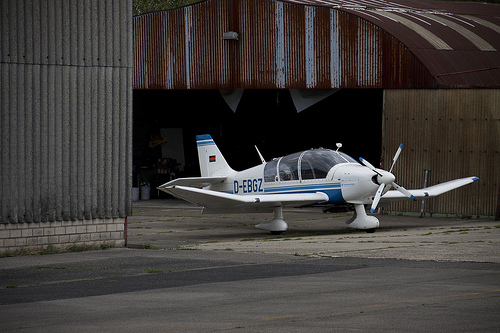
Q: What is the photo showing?
A: It is showing a hangar.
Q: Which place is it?
A: It is a hangar.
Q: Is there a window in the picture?
A: Yes, there are windows.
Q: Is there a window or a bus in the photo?
A: Yes, there are windows.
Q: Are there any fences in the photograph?
A: No, there are no fences.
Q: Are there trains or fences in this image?
A: No, there are no fences or trains.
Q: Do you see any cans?
A: No, there are no cans.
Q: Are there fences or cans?
A: No, there are no cans or fences.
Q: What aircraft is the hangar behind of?
A: The hangar is behind the plane.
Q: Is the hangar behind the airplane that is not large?
A: Yes, the hangar is behind the airplane.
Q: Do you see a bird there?
A: No, there are no birds.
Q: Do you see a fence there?
A: No, there are no fences.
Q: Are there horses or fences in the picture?
A: No, there are no fences or horses.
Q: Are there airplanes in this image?
A: Yes, there is an airplane.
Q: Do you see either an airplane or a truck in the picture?
A: Yes, there is an airplane.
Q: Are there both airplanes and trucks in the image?
A: No, there is an airplane but no trucks.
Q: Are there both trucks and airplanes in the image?
A: No, there is an airplane but no trucks.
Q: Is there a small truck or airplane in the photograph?
A: Yes, there is a small airplane.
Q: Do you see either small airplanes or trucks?
A: Yes, there is a small airplane.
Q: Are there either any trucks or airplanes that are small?
A: Yes, the airplane is small.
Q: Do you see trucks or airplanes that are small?
A: Yes, the airplane is small.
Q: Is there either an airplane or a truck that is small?
A: Yes, the airplane is small.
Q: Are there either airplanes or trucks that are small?
A: Yes, the airplane is small.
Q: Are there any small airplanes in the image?
A: Yes, there is a small airplane.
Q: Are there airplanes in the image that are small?
A: Yes, there is an airplane that is small.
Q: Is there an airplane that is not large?
A: Yes, there is a small airplane.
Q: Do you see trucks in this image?
A: No, there are no trucks.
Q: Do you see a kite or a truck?
A: No, there are no trucks or kites.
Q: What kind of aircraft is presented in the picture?
A: The aircraft is an airplane.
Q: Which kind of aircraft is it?
A: The aircraft is an airplane.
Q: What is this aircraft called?
A: This is an airplane.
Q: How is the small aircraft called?
A: The aircraft is an airplane.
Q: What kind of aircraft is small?
A: The aircraft is an airplane.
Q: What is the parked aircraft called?
A: The aircraft is an airplane.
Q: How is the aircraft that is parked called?
A: The aircraft is an airplane.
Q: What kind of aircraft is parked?
A: The aircraft is an airplane.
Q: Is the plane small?
A: Yes, the plane is small.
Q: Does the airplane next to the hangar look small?
A: Yes, the airplane is small.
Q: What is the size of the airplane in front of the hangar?
A: The plane is small.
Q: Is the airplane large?
A: No, the airplane is small.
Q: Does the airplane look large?
A: No, the airplane is small.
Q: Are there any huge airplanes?
A: No, there is an airplane but it is small.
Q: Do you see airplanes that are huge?
A: No, there is an airplane but it is small.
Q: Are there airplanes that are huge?
A: No, there is an airplane but it is small.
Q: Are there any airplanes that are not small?
A: No, there is an airplane but it is small.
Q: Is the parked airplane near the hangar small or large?
A: The plane is small.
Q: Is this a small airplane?
A: Yes, this is a small airplane.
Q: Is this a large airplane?
A: No, this is a small airplane.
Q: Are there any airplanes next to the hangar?
A: Yes, there is an airplane next to the hangar.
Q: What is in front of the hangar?
A: The airplane is in front of the hangar.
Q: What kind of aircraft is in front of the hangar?
A: The aircraft is an airplane.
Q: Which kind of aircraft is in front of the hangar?
A: The aircraft is an airplane.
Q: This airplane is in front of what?
A: The airplane is in front of the hangar.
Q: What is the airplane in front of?
A: The airplane is in front of the hangar.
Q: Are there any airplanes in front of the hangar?
A: Yes, there is an airplane in front of the hangar.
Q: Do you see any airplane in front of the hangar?
A: Yes, there is an airplane in front of the hangar.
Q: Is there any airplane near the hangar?
A: Yes, there is an airplane near the hangar.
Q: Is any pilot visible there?
A: No, there are no pilots.